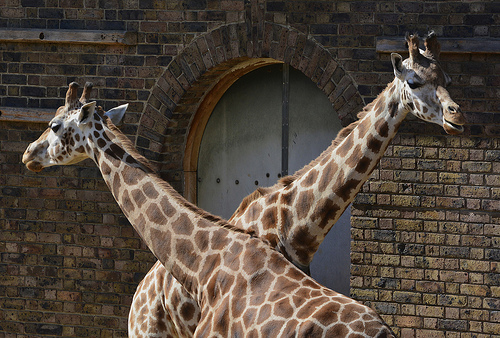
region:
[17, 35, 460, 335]
two giraffes standing in front of door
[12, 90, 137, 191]
head of spotted giraffe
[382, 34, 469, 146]
head of giraffe with horns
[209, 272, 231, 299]
brown spot on giraffe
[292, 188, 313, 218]
brown spot on giraffe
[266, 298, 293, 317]
brown spot on giraffe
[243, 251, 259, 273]
brown spot on giraffe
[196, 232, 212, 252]
brown spot on giraffe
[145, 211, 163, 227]
brown spot on giraffe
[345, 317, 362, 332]
brown spot on giraffe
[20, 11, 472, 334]
Two giraffes facing opposite directions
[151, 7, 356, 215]
Gray double door in brick building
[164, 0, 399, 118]
Archway made of bricks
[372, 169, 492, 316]
Brown brick building wall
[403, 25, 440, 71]
Horns on giraffe's head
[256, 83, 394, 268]
Very long neck of giraffe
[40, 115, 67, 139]
Large pretty eye of giraffe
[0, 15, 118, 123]
Two white lines of brick in brown wall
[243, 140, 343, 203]
Short mane on back of giraffe's neck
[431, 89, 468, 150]
Nose and mouth area of giraffe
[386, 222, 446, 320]
a brick wall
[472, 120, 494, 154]
a brick wall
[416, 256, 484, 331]
a brick wall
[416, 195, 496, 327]
a brick wall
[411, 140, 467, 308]
a brick wall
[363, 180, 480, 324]
a brick wall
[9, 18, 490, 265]
Two Giraffes standing next to each other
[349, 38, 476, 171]
Giraffe standing in front of a building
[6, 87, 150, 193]
Giraffe looking straight ahead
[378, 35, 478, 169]
Giraffe looking southbound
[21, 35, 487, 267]
Giraffes looking away from each other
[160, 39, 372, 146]
Brick wall with arched frame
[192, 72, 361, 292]
Window with giraffes in front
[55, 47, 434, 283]
Two giraffes in front of a building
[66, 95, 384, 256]
Two giraffes standing neck and neck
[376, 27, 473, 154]
Giraffe with his mouth open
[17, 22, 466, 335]
the two giraffe's standing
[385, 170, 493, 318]
the brown brick wall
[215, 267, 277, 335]
the brown on the giraffe in the front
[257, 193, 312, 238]
the brown spots on the giraffe in the back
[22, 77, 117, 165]
the giraffe head facing left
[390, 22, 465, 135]
the giraffe head facing right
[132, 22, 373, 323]
the arch in the brick wall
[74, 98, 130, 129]
the giraffe's ear on the giraffe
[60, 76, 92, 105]
the horns on the giraffe's head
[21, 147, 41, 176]
the giraffe's mouth